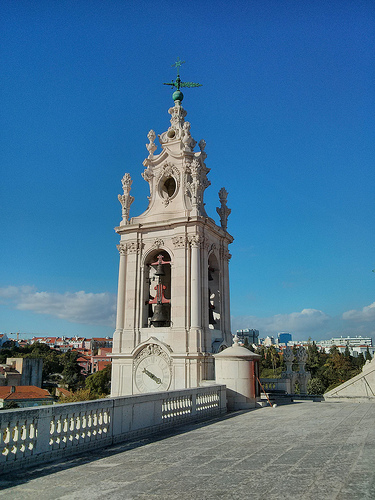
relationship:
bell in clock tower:
[141, 256, 173, 288] [111, 54, 236, 396]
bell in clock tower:
[146, 255, 171, 327] [111, 54, 236, 396]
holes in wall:
[159, 390, 217, 417] [0, 379, 232, 475]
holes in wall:
[1, 409, 116, 455] [0, 379, 232, 475]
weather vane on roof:
[155, 65, 200, 100] [115, 100, 233, 242]